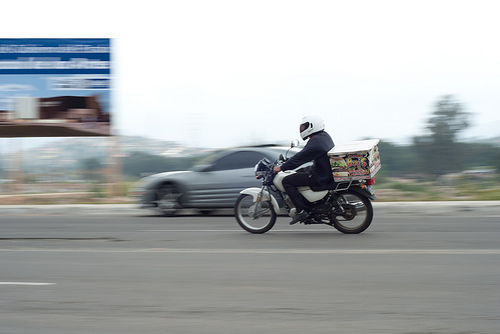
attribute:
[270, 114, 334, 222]
person — riding, black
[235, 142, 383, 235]
bike — strapped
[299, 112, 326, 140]
helmet — white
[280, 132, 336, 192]
jacket — blue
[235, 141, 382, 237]
motorcycle — white, riding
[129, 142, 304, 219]
car — silver, running, blurred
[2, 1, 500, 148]
sky — blue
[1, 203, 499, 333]
road — rough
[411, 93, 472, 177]
tree — green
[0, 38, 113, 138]
sign — multicolored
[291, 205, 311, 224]
shoes — black